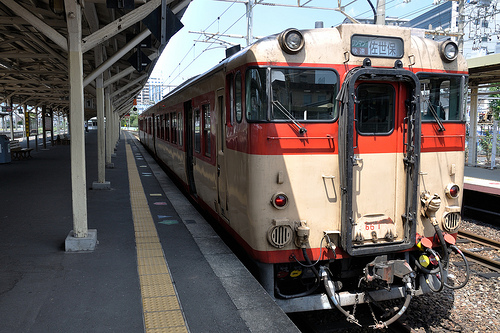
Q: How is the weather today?
A: It is clear.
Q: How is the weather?
A: It is clear.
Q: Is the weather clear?
A: Yes, it is clear.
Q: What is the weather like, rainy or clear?
A: It is clear.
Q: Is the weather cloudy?
A: No, it is clear.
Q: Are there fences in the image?
A: No, there are no fences.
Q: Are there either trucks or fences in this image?
A: No, there are no fences or trucks.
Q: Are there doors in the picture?
A: Yes, there is a door.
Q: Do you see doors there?
A: Yes, there is a door.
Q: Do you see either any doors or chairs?
A: Yes, there is a door.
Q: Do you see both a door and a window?
A: Yes, there are both a door and a window.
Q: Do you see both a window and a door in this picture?
A: Yes, there are both a door and a window.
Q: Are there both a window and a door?
A: Yes, there are both a door and a window.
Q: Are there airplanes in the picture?
A: No, there are no airplanes.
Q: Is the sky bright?
A: Yes, the sky is bright.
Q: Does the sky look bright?
A: Yes, the sky is bright.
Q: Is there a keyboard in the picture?
A: No, there are no keyboards.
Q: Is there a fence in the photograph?
A: No, there are no fences.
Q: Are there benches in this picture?
A: Yes, there is a bench.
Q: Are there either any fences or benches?
A: Yes, there is a bench.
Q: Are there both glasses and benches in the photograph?
A: No, there is a bench but no glasses.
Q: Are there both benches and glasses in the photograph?
A: No, there is a bench but no glasses.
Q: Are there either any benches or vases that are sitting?
A: Yes, the bench is sitting.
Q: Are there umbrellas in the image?
A: No, there are no umbrellas.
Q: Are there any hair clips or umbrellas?
A: No, there are no umbrellas or hair clips.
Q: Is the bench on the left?
A: Yes, the bench is on the left of the image.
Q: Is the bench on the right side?
A: No, the bench is on the left of the image.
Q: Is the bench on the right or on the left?
A: The bench is on the left of the image.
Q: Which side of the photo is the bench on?
A: The bench is on the left of the image.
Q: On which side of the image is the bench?
A: The bench is on the left of the image.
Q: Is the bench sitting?
A: Yes, the bench is sitting.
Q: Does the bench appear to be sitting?
A: Yes, the bench is sitting.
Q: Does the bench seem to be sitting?
A: Yes, the bench is sitting.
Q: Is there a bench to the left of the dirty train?
A: Yes, there is a bench to the left of the train.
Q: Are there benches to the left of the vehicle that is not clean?
A: Yes, there is a bench to the left of the train.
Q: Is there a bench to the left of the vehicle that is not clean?
A: Yes, there is a bench to the left of the train.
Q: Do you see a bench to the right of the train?
A: No, the bench is to the left of the train.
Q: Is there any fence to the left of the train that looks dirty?
A: No, there is a bench to the left of the train.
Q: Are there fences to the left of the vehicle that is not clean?
A: No, there is a bench to the left of the train.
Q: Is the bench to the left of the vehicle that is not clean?
A: Yes, the bench is to the left of the train.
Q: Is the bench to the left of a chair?
A: No, the bench is to the left of the train.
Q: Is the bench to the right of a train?
A: No, the bench is to the left of a train.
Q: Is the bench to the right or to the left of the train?
A: The bench is to the left of the train.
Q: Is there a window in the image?
A: Yes, there is a window.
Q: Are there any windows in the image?
A: Yes, there is a window.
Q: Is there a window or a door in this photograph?
A: Yes, there is a window.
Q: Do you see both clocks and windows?
A: No, there is a window but no clocks.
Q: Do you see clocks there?
A: No, there are no clocks.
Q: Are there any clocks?
A: No, there are no clocks.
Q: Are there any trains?
A: Yes, there is a train.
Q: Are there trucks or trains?
A: Yes, there is a train.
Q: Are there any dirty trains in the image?
A: Yes, there is a dirty train.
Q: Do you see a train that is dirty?
A: Yes, there is a train that is dirty.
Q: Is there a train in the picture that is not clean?
A: Yes, there is a dirty train.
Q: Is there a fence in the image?
A: No, there are no fences.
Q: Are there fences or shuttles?
A: No, there are no fences or shuttles.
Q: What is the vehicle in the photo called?
A: The vehicle is a train.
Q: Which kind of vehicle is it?
A: The vehicle is a train.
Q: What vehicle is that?
A: This is a train.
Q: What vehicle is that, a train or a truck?
A: This is a train.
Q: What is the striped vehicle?
A: The vehicle is a train.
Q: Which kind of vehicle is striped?
A: The vehicle is a train.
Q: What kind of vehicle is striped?
A: The vehicle is a train.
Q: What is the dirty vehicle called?
A: The vehicle is a train.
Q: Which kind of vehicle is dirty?
A: The vehicle is a train.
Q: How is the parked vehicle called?
A: The vehicle is a train.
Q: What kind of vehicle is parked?
A: The vehicle is a train.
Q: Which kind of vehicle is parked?
A: The vehicle is a train.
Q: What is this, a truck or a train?
A: This is a train.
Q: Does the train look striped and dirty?
A: Yes, the train is striped and dirty.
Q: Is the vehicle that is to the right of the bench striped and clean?
A: No, the train is striped but dirty.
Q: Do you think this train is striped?
A: Yes, the train is striped.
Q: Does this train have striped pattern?
A: Yes, the train is striped.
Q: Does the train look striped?
A: Yes, the train is striped.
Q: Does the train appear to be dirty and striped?
A: Yes, the train is dirty and striped.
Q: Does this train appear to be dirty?
A: Yes, the train is dirty.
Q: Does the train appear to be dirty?
A: Yes, the train is dirty.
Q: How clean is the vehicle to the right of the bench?
A: The train is dirty.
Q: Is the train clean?
A: No, the train is dirty.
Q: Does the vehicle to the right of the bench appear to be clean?
A: No, the train is dirty.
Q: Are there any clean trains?
A: No, there is a train but it is dirty.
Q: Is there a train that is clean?
A: No, there is a train but it is dirty.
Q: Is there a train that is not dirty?
A: No, there is a train but it is dirty.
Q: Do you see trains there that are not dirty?
A: No, there is a train but it is dirty.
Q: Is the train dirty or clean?
A: The train is dirty.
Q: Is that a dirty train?
A: Yes, that is a dirty train.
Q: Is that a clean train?
A: No, that is a dirty train.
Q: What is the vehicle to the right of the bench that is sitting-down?
A: The vehicle is a train.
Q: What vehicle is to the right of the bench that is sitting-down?
A: The vehicle is a train.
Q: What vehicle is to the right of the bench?
A: The vehicle is a train.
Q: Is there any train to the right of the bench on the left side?
A: Yes, there is a train to the right of the bench.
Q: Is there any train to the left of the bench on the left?
A: No, the train is to the right of the bench.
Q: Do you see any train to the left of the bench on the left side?
A: No, the train is to the right of the bench.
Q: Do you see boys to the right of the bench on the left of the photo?
A: No, there is a train to the right of the bench.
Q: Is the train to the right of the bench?
A: Yes, the train is to the right of the bench.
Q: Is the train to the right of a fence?
A: No, the train is to the right of the bench.